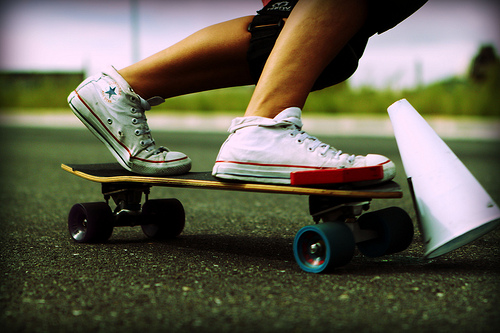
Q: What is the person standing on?
A: A skateboard.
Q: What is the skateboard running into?
A: A cone.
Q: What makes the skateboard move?
A: The wheels.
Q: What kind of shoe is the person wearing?
A: Converse.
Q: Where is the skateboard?
A: On the road.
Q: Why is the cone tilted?
A: The skateboard hit it.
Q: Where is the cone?
A: In the road.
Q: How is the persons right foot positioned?
A: Flat.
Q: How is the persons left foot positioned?
A: Heel up.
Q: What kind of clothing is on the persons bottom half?
A: Shorts.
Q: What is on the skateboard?
A: Feet.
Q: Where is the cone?
A: On the road.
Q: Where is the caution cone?
A: On the road.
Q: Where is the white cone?
A: On the road.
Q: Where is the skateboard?
A: On the road.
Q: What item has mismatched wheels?
A: The skateboard.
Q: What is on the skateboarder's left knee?
A: The knee pad.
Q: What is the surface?
A: The green artificial turf.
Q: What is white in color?
A: The shoes.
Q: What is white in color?
A: The megaphone.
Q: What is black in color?
A: The skateboard.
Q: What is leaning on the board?
A: One foot.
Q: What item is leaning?
A: The megaphone.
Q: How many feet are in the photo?
A: Two.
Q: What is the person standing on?
A: Skateboard.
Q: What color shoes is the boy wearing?
A: White.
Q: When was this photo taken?
A: Daytime.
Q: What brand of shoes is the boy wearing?
A: Converse.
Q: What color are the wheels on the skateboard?
A: Blue.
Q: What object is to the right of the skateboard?
A: Cone.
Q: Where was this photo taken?
A: A skateboard park.